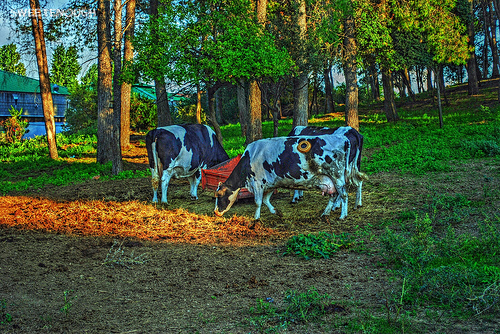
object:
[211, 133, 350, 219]
cow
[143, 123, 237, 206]
cow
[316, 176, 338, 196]
udder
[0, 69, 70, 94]
roof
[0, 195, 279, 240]
light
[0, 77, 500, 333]
ground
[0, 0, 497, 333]
background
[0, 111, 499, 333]
grass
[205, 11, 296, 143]
tree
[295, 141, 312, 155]
object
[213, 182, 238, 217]
head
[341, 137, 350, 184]
tail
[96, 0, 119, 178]
tree trunk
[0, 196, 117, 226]
grass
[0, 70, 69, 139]
building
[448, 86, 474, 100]
patch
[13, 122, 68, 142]
wall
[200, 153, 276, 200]
trough